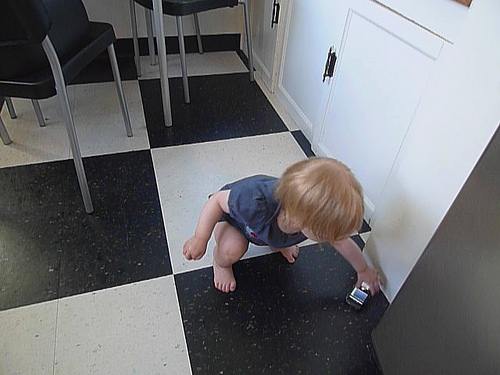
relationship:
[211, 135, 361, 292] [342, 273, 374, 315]
kid with toy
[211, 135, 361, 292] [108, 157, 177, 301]
kid on floor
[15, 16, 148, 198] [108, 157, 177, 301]
chair on floor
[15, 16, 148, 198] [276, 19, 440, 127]
chair near door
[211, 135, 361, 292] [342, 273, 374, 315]
kid playing with toy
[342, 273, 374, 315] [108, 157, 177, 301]
toy on floor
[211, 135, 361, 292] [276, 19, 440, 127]
kid near door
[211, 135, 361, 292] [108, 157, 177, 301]
kid near floor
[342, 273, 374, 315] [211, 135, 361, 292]
toy with kid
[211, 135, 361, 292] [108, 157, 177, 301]
kid in floor